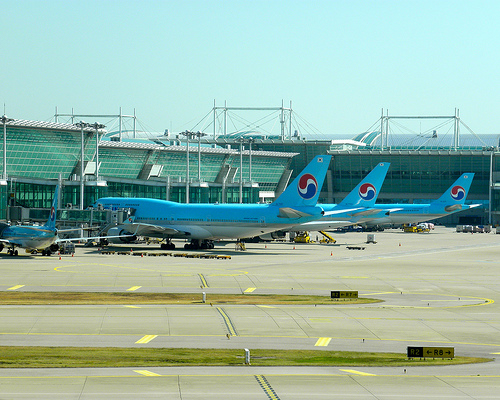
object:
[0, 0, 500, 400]
airport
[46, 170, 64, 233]
stabilizer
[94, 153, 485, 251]
jet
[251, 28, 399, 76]
sky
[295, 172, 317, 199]
logo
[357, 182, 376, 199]
logo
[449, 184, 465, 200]
logo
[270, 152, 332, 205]
vertical stabilizer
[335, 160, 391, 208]
vertical stabilizer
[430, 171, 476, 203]
vertical stabilizer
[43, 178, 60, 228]
vertical stabilizer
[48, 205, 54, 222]
logo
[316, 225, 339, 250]
stairs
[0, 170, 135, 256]
plane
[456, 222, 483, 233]
carts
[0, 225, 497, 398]
pavement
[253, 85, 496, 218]
building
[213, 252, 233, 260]
cart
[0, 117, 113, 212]
building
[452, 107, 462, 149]
poles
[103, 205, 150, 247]
jet engine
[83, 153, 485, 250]
aircraft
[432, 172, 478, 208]
stabilizer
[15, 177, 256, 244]
gates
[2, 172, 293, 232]
terminal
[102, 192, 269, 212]
top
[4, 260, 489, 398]
lines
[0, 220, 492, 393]
parking lot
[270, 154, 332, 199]
tail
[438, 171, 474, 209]
tail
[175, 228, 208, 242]
gears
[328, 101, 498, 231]
building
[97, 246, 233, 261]
carriers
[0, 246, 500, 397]
runway